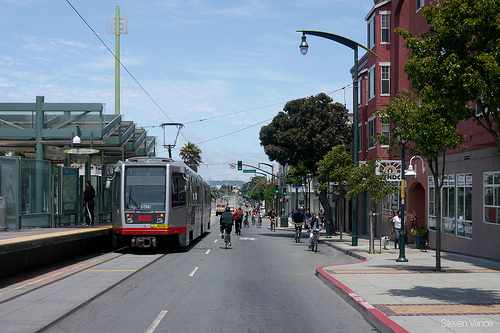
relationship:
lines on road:
[179, 261, 197, 291] [251, 263, 302, 304]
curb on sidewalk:
[326, 277, 348, 298] [400, 275, 441, 314]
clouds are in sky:
[196, 80, 220, 120] [164, 14, 256, 73]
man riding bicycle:
[218, 206, 236, 245] [216, 225, 234, 247]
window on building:
[371, 8, 398, 52] [337, 5, 416, 175]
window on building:
[371, 60, 398, 99] [337, 5, 416, 175]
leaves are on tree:
[390, 28, 430, 141] [380, 29, 463, 270]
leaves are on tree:
[390, 28, 430, 141] [426, 2, 497, 140]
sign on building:
[371, 160, 403, 182] [345, 3, 439, 245]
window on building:
[376, 8, 397, 49] [337, 4, 443, 244]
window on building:
[362, 9, 378, 52] [331, 3, 437, 231]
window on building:
[373, 62, 396, 99] [331, 3, 437, 231]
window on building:
[365, 64, 375, 105] [331, 8, 462, 243]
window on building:
[352, 77, 363, 112] [331, 3, 437, 231]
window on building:
[377, 110, 392, 151] [330, 0, 448, 242]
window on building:
[365, 119, 378, 150] [341, 4, 424, 244]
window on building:
[475, 165, 498, 246] [333, 4, 497, 274]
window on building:
[451, 174, 478, 243] [333, 4, 497, 274]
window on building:
[424, 173, 439, 234] [333, 4, 497, 274]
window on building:
[440, 170, 455, 240] [333, 4, 497, 274]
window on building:
[365, 119, 378, 151] [331, 0, 500, 266]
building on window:
[331, 0, 500, 266] [377, 61, 392, 98]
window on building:
[376, 8, 397, 49] [350, 3, 499, 257]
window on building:
[362, 9, 378, 52] [342, 3, 492, 239]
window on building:
[362, 9, 378, 49] [350, 3, 499, 257]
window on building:
[377, 110, 393, 150] [345, 0, 483, 265]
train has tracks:
[108, 154, 187, 254] [0, 249, 129, 330]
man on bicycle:
[215, 201, 237, 241] [214, 224, 235, 250]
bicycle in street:
[214, 224, 235, 250] [2, 209, 377, 331]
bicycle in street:
[302, 229, 321, 254] [2, 209, 377, 331]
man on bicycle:
[302, 211, 321, 244] [302, 229, 321, 254]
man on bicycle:
[286, 204, 307, 233] [290, 220, 304, 244]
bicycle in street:
[290, 220, 304, 244] [2, 194, 374, 331]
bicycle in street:
[264, 214, 280, 231] [2, 194, 374, 331]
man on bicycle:
[266, 206, 276, 224] [264, 214, 280, 231]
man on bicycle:
[235, 206, 244, 224] [231, 219, 248, 239]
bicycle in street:
[231, 219, 248, 239] [2, 194, 374, 331]